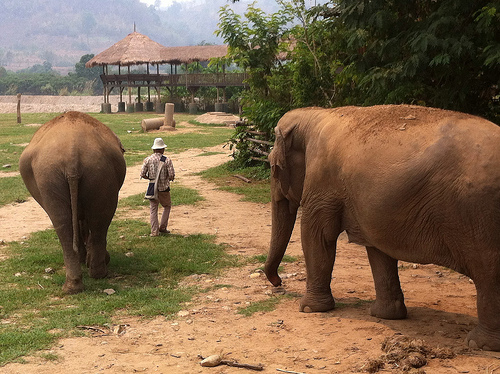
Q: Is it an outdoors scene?
A: Yes, it is outdoors.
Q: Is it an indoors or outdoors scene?
A: It is outdoors.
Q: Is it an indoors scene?
A: No, it is outdoors.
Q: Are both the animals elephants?
A: Yes, all the animals are elephants.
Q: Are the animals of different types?
A: No, all the animals are elephants.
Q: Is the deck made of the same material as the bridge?
A: Yes, both the deck and the bridge are made of wood.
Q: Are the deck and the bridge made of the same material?
A: Yes, both the deck and the bridge are made of wood.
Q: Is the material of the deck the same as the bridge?
A: Yes, both the deck and the bridge are made of wood.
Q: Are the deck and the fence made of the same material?
A: Yes, both the deck and the fence are made of wood.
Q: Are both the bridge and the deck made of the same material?
A: Yes, both the bridge and the deck are made of wood.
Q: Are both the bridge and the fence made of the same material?
A: Yes, both the bridge and the fence are made of wood.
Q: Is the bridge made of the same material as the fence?
A: Yes, both the bridge and the fence are made of wood.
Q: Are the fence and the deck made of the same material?
A: Yes, both the fence and the deck are made of wood.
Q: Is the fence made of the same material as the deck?
A: Yes, both the fence and the deck are made of wood.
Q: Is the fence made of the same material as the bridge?
A: Yes, both the fence and the bridge are made of wood.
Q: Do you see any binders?
A: No, there are no binders.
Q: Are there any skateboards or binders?
A: No, there are no binders or skateboards.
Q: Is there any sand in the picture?
A: Yes, there is sand.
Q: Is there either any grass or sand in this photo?
A: Yes, there is sand.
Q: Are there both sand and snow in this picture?
A: No, there is sand but no snow.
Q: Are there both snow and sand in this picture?
A: No, there is sand but no snow.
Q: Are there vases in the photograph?
A: No, there are no vases.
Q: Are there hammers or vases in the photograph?
A: No, there are no vases or hammers.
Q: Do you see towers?
A: No, there are no towers.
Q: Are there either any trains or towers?
A: No, there are no towers or trains.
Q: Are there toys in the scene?
A: No, there are no toys.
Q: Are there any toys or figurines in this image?
A: No, there are no toys or figurines.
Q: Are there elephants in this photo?
A: Yes, there is an elephant.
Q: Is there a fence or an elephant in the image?
A: Yes, there is an elephant.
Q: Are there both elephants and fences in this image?
A: Yes, there are both an elephant and a fence.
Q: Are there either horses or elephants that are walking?
A: Yes, the elephant is walking.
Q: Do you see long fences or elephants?
A: Yes, there is a long elephant.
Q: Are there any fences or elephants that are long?
A: Yes, the elephant is long.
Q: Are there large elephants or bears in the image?
A: Yes, there is a large elephant.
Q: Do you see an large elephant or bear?
A: Yes, there is a large elephant.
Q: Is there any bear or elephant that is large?
A: Yes, the elephant is large.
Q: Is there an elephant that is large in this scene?
A: Yes, there is a large elephant.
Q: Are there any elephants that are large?
A: Yes, there is an elephant that is large.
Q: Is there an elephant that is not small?
A: Yes, there is a large elephant.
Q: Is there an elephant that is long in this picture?
A: Yes, there is a long elephant.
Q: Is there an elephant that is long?
A: Yes, there is an elephant that is long.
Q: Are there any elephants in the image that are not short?
A: Yes, there is a long elephant.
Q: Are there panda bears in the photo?
A: No, there are no panda bears.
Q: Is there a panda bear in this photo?
A: No, there are no pandas.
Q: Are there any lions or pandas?
A: No, there are no pandas or lions.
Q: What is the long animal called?
A: The animal is an elephant.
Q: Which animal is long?
A: The animal is an elephant.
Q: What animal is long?
A: The animal is an elephant.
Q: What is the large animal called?
A: The animal is an elephant.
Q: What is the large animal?
A: The animal is an elephant.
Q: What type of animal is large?
A: The animal is an elephant.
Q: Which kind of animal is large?
A: The animal is an elephant.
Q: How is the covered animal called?
A: The animal is an elephant.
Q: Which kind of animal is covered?
A: The animal is an elephant.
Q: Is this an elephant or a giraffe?
A: This is an elephant.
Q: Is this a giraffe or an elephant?
A: This is an elephant.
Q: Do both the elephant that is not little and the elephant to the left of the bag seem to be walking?
A: Yes, both the elephant and the elephant are walking.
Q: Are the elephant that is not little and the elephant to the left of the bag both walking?
A: Yes, both the elephant and the elephant are walking.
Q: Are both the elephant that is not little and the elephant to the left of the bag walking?
A: Yes, both the elephant and the elephant are walking.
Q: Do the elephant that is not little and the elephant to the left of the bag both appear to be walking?
A: Yes, both the elephant and the elephant are walking.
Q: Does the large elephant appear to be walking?
A: Yes, the elephant is walking.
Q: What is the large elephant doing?
A: The elephant is walking.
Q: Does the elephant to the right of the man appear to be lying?
A: No, the elephant is walking.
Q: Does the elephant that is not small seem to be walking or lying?
A: The elephant is walking.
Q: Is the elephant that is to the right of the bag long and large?
A: Yes, the elephant is long and large.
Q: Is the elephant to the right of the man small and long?
A: No, the elephant is long but large.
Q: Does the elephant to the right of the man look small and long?
A: No, the elephant is long but large.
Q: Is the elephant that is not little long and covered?
A: Yes, the elephant is long and covered.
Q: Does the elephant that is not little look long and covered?
A: Yes, the elephant is long and covered.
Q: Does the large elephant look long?
A: Yes, the elephant is long.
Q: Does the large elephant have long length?
A: Yes, the elephant is long.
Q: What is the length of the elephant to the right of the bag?
A: The elephant is long.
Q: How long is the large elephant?
A: The elephant is long.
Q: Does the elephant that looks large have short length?
A: No, the elephant is long.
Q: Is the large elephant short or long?
A: The elephant is long.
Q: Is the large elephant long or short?
A: The elephant is long.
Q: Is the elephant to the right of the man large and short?
A: No, the elephant is large but long.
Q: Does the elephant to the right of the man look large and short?
A: No, the elephant is large but long.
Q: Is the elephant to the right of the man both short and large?
A: No, the elephant is large but long.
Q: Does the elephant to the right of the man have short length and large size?
A: No, the elephant is large but long.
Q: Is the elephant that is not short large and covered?
A: Yes, the elephant is large and covered.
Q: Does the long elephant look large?
A: Yes, the elephant is large.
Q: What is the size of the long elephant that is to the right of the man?
A: The elephant is large.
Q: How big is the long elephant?
A: The elephant is large.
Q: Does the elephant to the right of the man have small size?
A: No, the elephant is large.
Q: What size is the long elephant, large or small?
A: The elephant is large.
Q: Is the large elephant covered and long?
A: Yes, the elephant is covered and long.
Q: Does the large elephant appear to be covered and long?
A: Yes, the elephant is covered and long.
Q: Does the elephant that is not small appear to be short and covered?
A: No, the elephant is covered but long.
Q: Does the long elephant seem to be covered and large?
A: Yes, the elephant is covered and large.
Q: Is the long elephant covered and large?
A: Yes, the elephant is covered and large.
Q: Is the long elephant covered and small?
A: No, the elephant is covered but large.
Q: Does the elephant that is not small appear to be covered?
A: Yes, the elephant is covered.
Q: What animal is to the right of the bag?
A: The animal is an elephant.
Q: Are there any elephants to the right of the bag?
A: Yes, there is an elephant to the right of the bag.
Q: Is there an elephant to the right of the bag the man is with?
A: Yes, there is an elephant to the right of the bag.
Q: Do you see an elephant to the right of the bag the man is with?
A: Yes, there is an elephant to the right of the bag.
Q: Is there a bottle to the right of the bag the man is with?
A: No, there is an elephant to the right of the bag.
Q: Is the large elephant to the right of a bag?
A: Yes, the elephant is to the right of a bag.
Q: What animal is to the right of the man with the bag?
A: The animal is an elephant.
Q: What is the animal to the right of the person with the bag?
A: The animal is an elephant.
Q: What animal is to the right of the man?
A: The animal is an elephant.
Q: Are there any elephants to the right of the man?
A: Yes, there is an elephant to the right of the man.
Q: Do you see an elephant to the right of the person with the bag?
A: Yes, there is an elephant to the right of the man.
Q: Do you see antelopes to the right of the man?
A: No, there is an elephant to the right of the man.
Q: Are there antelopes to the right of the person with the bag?
A: No, there is an elephant to the right of the man.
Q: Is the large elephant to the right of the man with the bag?
A: Yes, the elephant is to the right of the man.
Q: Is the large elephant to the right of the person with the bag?
A: Yes, the elephant is to the right of the man.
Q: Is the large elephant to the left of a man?
A: No, the elephant is to the right of a man.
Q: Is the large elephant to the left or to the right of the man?
A: The elephant is to the right of the man.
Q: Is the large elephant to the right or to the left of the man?
A: The elephant is to the right of the man.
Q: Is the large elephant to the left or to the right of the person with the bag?
A: The elephant is to the right of the man.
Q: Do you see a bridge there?
A: Yes, there is a bridge.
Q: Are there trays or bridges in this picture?
A: Yes, there is a bridge.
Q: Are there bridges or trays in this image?
A: Yes, there is a bridge.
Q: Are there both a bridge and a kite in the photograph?
A: No, there is a bridge but no kites.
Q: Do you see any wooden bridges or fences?
A: Yes, there is a wood bridge.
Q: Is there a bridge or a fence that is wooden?
A: Yes, the bridge is wooden.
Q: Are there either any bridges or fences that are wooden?
A: Yes, the bridge is wooden.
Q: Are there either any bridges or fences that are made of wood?
A: Yes, the bridge is made of wood.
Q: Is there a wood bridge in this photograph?
A: Yes, there is a wood bridge.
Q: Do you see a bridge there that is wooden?
A: Yes, there is a bridge that is wooden.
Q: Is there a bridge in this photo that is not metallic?
A: Yes, there is a wooden bridge.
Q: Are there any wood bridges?
A: Yes, there is a bridge that is made of wood.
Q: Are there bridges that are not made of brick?
A: Yes, there is a bridge that is made of wood.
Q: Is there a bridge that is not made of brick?
A: Yes, there is a bridge that is made of wood.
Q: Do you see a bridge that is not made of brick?
A: Yes, there is a bridge that is made of wood.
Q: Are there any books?
A: No, there are no books.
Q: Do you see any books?
A: No, there are no books.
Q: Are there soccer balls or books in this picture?
A: No, there are no books or soccer balls.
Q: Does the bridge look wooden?
A: Yes, the bridge is wooden.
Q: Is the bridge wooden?
A: Yes, the bridge is wooden.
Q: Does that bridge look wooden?
A: Yes, the bridge is wooden.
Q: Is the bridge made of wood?
A: Yes, the bridge is made of wood.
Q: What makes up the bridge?
A: The bridge is made of wood.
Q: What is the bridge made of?
A: The bridge is made of wood.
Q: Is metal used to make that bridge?
A: No, the bridge is made of wood.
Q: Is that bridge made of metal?
A: No, the bridge is made of wood.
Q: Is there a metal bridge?
A: No, there is a bridge but it is made of wood.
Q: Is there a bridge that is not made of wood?
A: No, there is a bridge but it is made of wood.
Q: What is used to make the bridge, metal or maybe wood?
A: The bridge is made of wood.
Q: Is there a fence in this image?
A: Yes, there is a fence.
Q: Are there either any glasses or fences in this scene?
A: Yes, there is a fence.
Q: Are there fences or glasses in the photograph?
A: Yes, there is a fence.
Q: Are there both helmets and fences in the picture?
A: No, there is a fence but no helmets.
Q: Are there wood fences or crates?
A: Yes, there is a wood fence.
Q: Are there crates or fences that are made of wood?
A: Yes, the fence is made of wood.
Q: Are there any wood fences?
A: Yes, there is a wood fence.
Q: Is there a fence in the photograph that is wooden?
A: Yes, there is a fence that is wooden.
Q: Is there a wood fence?
A: Yes, there is a fence that is made of wood.